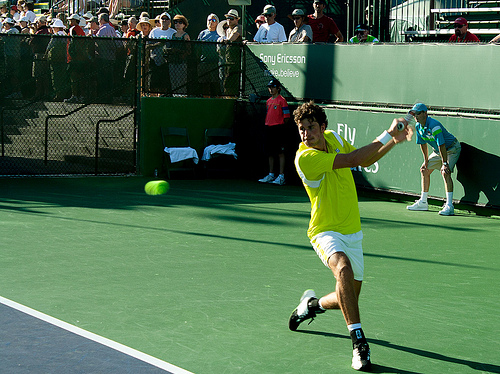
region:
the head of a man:
[290, 95, 333, 148]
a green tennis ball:
[141, 176, 174, 199]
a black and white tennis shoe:
[282, 282, 326, 334]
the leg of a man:
[311, 233, 363, 333]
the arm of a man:
[302, 138, 384, 179]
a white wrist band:
[375, 124, 392, 148]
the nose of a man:
[301, 123, 313, 140]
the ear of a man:
[318, 120, 329, 135]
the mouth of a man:
[298, 135, 316, 145]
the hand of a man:
[388, 113, 409, 135]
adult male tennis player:
[258, 85, 443, 372]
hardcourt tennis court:
[0, 159, 489, 368]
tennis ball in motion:
[133, 174, 188, 206]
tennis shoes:
[265, 279, 396, 368]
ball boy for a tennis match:
[390, 98, 467, 224]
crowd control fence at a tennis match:
[2, 15, 262, 195]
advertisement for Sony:
[252, 46, 309, 81]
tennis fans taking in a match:
[72, 0, 261, 107]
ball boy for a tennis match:
[255, 60, 289, 195]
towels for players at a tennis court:
[133, 110, 254, 197]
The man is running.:
[283, 98, 423, 373]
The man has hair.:
[275, 85, 337, 156]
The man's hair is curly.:
[282, 90, 343, 172]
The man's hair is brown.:
[285, 93, 351, 172]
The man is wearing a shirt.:
[291, 97, 374, 259]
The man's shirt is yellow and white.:
[284, 97, 368, 243]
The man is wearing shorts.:
[276, 97, 421, 370]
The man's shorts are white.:
[275, 90, 427, 372]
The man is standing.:
[249, 62, 297, 197]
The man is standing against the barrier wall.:
[401, 38, 498, 234]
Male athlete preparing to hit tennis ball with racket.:
[288, 103, 414, 368]